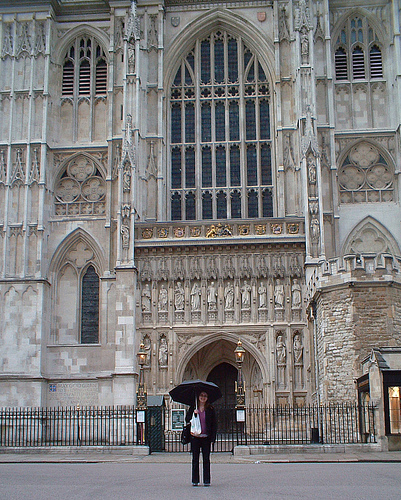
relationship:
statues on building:
[140, 277, 303, 311] [0, 0, 399, 441]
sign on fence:
[231, 405, 247, 421] [0, 402, 399, 446]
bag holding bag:
[189, 410, 202, 435] [189, 410, 202, 435]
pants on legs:
[191, 438, 211, 479] [175, 425, 244, 494]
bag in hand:
[189, 410, 202, 435] [192, 405, 200, 417]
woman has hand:
[183, 386, 219, 485] [192, 405, 200, 417]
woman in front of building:
[183, 386, 219, 485] [0, 0, 399, 441]